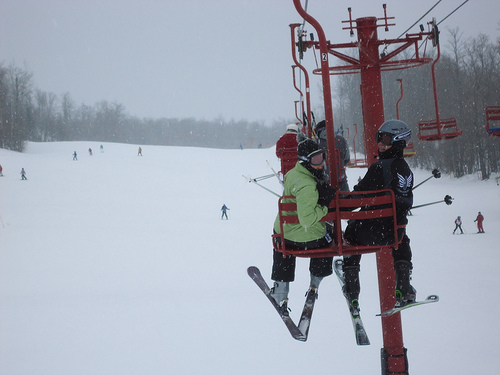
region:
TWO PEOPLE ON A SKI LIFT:
[269, 117, 436, 342]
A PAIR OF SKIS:
[246, 258, 323, 344]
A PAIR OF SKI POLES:
[415, 160, 455, 210]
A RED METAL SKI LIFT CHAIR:
[268, 178, 403, 264]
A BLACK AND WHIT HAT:
[286, 127, 330, 168]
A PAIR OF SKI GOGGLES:
[367, 125, 404, 149]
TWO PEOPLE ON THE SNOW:
[450, 206, 487, 239]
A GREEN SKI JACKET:
[266, 163, 337, 250]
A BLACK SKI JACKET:
[336, 157, 418, 254]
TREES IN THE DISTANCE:
[26, 86, 251, 154]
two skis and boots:
[251, 258, 326, 354]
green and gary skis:
[312, 284, 447, 374]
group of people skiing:
[0, 135, 169, 232]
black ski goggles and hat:
[295, 138, 328, 172]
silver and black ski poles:
[403, 155, 453, 236]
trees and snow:
[8, 82, 261, 149]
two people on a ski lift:
[230, 103, 422, 334]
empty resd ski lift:
[407, 110, 467, 155]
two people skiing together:
[408, 204, 490, 261]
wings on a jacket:
[350, 155, 435, 250]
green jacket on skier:
[276, 161, 328, 242]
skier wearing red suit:
[471, 210, 485, 234]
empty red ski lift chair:
[415, 116, 462, 141]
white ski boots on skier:
[268, 274, 323, 301]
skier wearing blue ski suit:
[218, 202, 230, 217]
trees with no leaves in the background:
[0, 61, 278, 148]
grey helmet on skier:
[376, 118, 411, 143]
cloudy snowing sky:
[8, 4, 283, 82]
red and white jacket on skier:
[453, 215, 463, 237]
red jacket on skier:
[276, 130, 299, 173]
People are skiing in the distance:
[6, 109, 257, 259]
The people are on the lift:
[257, 111, 440, 304]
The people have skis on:
[220, 231, 417, 373]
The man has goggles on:
[349, 103, 423, 175]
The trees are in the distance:
[3, 65, 296, 165]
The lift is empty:
[410, 95, 476, 160]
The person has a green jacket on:
[269, 157, 330, 257]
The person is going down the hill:
[206, 170, 238, 267]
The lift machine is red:
[288, 137, 425, 341]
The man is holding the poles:
[393, 152, 488, 254]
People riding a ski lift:
[264, 120, 423, 320]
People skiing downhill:
[1, 108, 238, 275]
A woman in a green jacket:
[262, 134, 335, 264]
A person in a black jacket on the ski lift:
[349, 118, 423, 254]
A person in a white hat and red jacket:
[271, 122, 301, 173]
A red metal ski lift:
[277, 20, 495, 373]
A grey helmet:
[352, 112, 419, 164]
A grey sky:
[57, 12, 271, 98]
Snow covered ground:
[14, 217, 217, 374]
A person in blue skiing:
[202, 194, 250, 228]